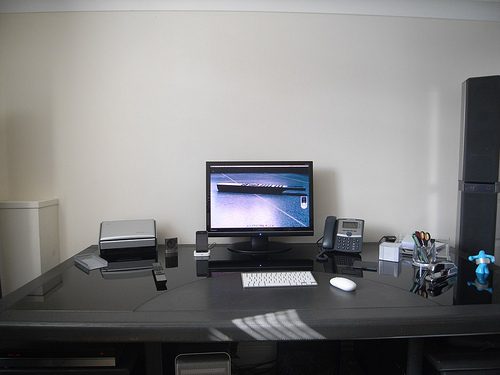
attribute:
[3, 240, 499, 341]
desk — black, black color, shiny, black colored, in office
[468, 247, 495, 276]
toy — blue figurine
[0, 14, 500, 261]
wall — white, colored white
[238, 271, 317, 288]
keyboard — white, white color, apple branded, small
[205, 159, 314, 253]
monitor — here, black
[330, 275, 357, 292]
mouse — wireless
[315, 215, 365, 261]
telephone — office type, black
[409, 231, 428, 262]
pens — here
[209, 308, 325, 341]
reflection — here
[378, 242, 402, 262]
paper block — here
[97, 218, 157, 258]
printer — silver, black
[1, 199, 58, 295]
cabinet — white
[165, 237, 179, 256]
speaker — black